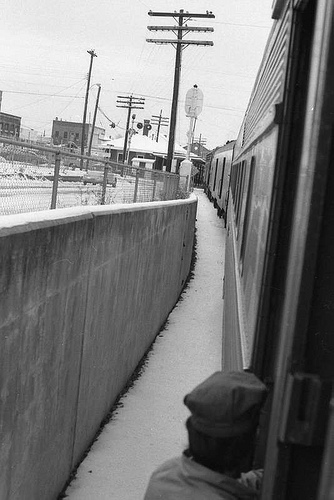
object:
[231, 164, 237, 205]
window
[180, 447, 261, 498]
collar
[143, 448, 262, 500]
coat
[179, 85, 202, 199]
pole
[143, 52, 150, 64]
line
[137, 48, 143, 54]
line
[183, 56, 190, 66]
line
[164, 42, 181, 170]
pole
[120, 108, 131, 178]
pole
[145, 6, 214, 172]
electric pole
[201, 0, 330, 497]
train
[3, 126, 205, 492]
train station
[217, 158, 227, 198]
window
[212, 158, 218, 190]
window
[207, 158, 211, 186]
window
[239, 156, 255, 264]
window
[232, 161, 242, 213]
window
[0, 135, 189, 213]
fence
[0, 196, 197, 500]
wall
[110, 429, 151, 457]
ice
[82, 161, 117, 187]
car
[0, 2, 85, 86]
sky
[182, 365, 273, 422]
hat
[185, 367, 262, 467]
head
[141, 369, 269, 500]
worker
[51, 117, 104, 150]
buildings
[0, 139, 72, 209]
fence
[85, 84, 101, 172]
poles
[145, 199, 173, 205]
snow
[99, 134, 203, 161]
roof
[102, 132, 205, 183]
building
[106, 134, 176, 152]
snow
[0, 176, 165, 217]
road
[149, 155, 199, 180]
shelter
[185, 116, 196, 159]
pole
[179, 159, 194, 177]
base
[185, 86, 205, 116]
sign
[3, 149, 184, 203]
metal fencing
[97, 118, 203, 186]
train depot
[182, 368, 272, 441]
cap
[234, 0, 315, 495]
doorway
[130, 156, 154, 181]
building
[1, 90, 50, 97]
wires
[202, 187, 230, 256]
tracks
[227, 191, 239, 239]
snow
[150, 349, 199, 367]
ground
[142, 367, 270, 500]
people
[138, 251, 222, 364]
snow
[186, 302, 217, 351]
ground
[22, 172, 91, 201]
street